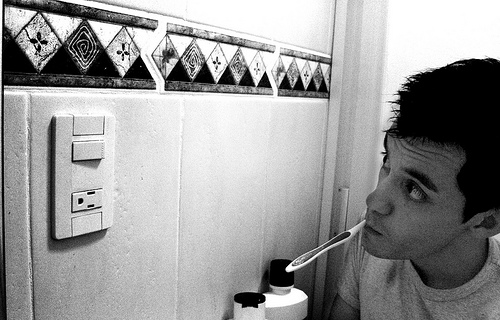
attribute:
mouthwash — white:
[252, 256, 307, 311]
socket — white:
[42, 119, 154, 273]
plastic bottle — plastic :
[260, 259, 310, 319]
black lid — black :
[268, 258, 293, 287]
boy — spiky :
[328, 56, 498, 318]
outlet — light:
[42, 110, 118, 250]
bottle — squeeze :
[221, 289, 318, 317]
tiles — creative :
[7, 6, 385, 115]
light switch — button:
[38, 104, 116, 261]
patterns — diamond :
[140, 52, 322, 97]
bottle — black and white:
[262, 255, 297, 296]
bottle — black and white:
[223, 288, 271, 318]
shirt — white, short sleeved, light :
[334, 224, 498, 319]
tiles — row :
[7, 4, 337, 104]